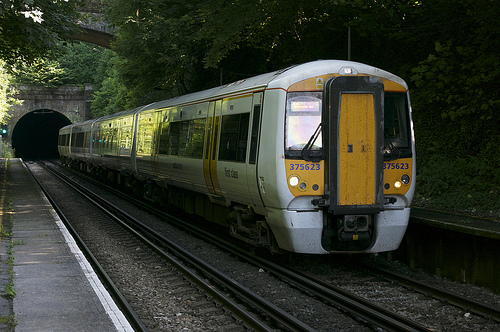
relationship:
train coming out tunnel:
[55, 60, 416, 254] [11, 108, 74, 161]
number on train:
[286, 161, 323, 171] [55, 60, 416, 254]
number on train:
[382, 159, 414, 174] [55, 60, 416, 254]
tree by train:
[417, 44, 493, 157] [55, 60, 416, 254]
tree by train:
[86, 57, 139, 119] [55, 60, 416, 254]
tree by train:
[111, 24, 178, 95] [55, 60, 416, 254]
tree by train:
[193, 0, 313, 71] [55, 60, 416, 254]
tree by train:
[0, 1, 81, 84] [55, 60, 416, 254]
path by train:
[4, 158, 130, 327] [55, 60, 416, 254]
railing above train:
[0, 1, 121, 46] [55, 60, 416, 254]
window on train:
[61, 133, 68, 144] [55, 60, 416, 254]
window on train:
[75, 131, 84, 147] [55, 60, 416, 254]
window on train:
[89, 132, 102, 146] [55, 60, 416, 254]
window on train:
[107, 129, 118, 151] [55, 60, 416, 254]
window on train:
[218, 112, 251, 163] [55, 60, 416, 254]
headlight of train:
[289, 176, 301, 186] [55, 60, 416, 254]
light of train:
[300, 181, 305, 196] [55, 60, 416, 254]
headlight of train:
[394, 181, 403, 188] [55, 60, 416, 254]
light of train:
[400, 173, 410, 184] [55, 60, 416, 254]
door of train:
[203, 99, 223, 204] [55, 60, 416, 254]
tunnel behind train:
[2, 81, 94, 161] [55, 60, 416, 254]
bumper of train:
[265, 207, 411, 254] [55, 60, 416, 254]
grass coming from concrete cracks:
[0, 157, 13, 330] [1, 157, 12, 329]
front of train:
[263, 60, 424, 260] [19, 69, 437, 264]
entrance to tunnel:
[13, 109, 71, 157] [12, 105, 87, 161]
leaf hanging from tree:
[62, 42, 68, 45] [0, 0, 82, 74]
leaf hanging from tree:
[71, 43, 75, 45] [0, 0, 82, 74]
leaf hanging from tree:
[8, 60, 13, 63] [0, 0, 82, 74]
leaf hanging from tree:
[39, 65, 44, 69] [0, 0, 82, 74]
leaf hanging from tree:
[28, 49, 33, 51] [0, 0, 82, 74]